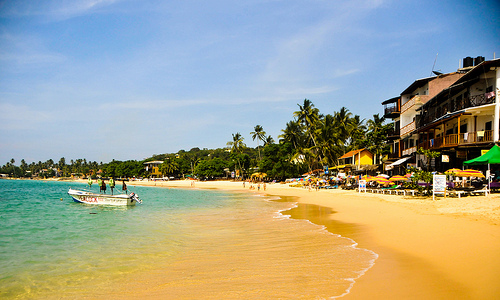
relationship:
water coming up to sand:
[6, 186, 66, 244] [395, 194, 489, 271]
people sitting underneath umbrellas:
[306, 167, 499, 197] [303, 168, 487, 182]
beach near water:
[224, 187, 469, 290] [0, 175, 237, 280]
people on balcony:
[421, 122, 443, 143] [439, 127, 482, 149]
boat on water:
[69, 188, 141, 209] [2, 179, 378, 299]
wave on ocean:
[245, 183, 379, 298] [2, 172, 359, 298]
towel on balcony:
[463, 129, 468, 140] [458, 129, 493, 145]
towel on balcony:
[476, 128, 484, 138] [458, 129, 493, 145]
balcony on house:
[441, 131, 489, 147] [424, 68, 498, 175]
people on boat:
[302, 150, 439, 206] [70, 179, 134, 212]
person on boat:
[95, 172, 109, 192] [65, 184, 143, 211]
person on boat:
[105, 172, 119, 194] [65, 184, 143, 211]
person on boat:
[117, 177, 130, 193] [65, 184, 143, 211]